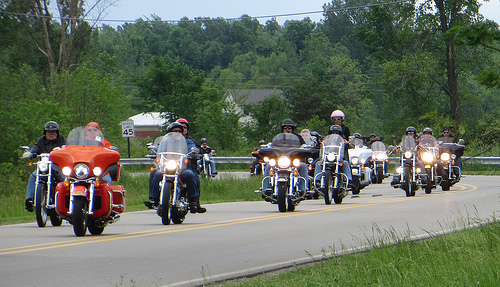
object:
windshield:
[63, 126, 104, 146]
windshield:
[155, 132, 187, 157]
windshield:
[270, 132, 300, 149]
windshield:
[318, 131, 343, 147]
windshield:
[415, 134, 437, 149]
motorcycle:
[309, 131, 354, 203]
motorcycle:
[409, 136, 441, 191]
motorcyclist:
[264, 112, 311, 210]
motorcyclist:
[388, 116, 423, 200]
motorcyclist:
[444, 117, 463, 179]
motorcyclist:
[151, 117, 191, 217]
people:
[325, 109, 354, 133]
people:
[77, 116, 112, 146]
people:
[151, 122, 201, 218]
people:
[257, 116, 312, 213]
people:
[350, 133, 367, 158]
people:
[398, 124, 420, 159]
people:
[421, 128, 436, 153]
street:
[2, 186, 499, 281]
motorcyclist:
[24, 68, 474, 235]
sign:
[112, 109, 154, 151]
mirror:
[188, 144, 225, 164]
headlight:
[67, 157, 92, 185]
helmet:
[326, 110, 342, 120]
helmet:
[168, 114, 175, 124]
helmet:
[43, 116, 58, 126]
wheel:
[74, 199, 84, 234]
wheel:
[160, 175, 168, 222]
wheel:
[277, 180, 287, 210]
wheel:
[322, 170, 329, 201]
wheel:
[404, 167, 411, 195]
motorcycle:
[17, 138, 64, 223]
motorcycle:
[256, 129, 312, 212]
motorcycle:
[388, 136, 427, 196]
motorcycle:
[439, 132, 465, 192]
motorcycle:
[55, 124, 117, 239]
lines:
[2, 157, 476, 263]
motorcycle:
[152, 135, 206, 217]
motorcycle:
[392, 135, 424, 196]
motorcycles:
[34, 103, 459, 234]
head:
[43, 120, 59, 139]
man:
[23, 118, 65, 211]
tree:
[17, 3, 103, 89]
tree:
[142, 54, 208, 127]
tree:
[289, 67, 362, 131]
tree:
[416, 0, 481, 140]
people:
[18, 97, 471, 236]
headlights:
[157, 148, 185, 180]